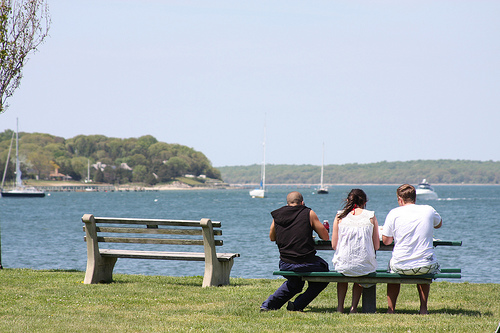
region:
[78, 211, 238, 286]
Cement and wood bench overlooking lake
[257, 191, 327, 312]
Man in black shirt sitting on bench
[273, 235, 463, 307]
Green picnic table near lake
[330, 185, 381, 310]
Lady in white blouse sitting on bench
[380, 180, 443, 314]
Man in white t-shirt sitting on bench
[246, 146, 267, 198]
White sailboat on lake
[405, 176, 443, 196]
White motorboat on lake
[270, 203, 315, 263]
Black shirt on man on picnic table bench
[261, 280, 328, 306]
Blue pants on man on picnic table bench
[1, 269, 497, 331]
Green grass on bank of lake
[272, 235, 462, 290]
a green picnic table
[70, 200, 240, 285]
a gray park bench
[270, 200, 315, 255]
a man's black tank top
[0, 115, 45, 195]
a black and white boat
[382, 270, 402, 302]
the leg of a man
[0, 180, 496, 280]
blue water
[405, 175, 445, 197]
a white boat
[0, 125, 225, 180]
a large section of green trees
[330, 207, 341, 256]
the arm of a woman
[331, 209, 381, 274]
a woman's sleeveless shirt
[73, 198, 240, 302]
Empty, cement park bench.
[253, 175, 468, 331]
Three people sitting at a picnic table.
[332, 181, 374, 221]
Woman with long brown hair.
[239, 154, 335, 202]
Boats traveling in the water.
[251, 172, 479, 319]
Three people eating at a waterside location.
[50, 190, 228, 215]
Blue water in the harbor.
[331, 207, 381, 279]
Flowing white shirt being worn by a woman.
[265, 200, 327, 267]
Black hooded tank top being worn by a man.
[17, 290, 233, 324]
Grass growing on the ground in the park.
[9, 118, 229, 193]
Shoreline covered in growing trees.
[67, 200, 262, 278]
A empty bench by the water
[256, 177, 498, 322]
Three friends sit at a picnic table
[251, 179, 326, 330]
The man is bald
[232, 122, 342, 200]
Sailboats are parked in the water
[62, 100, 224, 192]
The land is full of trees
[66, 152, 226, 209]
There is a small beach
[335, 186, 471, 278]
The woman and man wear white shirts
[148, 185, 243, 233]
The water is calm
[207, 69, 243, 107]
The sky is blue with no clouds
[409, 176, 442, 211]
A speed boat is in the water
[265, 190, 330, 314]
man sitting on a bench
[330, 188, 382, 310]
woman sitting on a bench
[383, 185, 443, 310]
man sitting on a bench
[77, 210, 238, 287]
a wooden park bench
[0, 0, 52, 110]
dead branches on a tree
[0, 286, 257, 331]
short light green grass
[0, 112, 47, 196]
a sail boat with a large mast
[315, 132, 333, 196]
a sail boat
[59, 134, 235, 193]
trees on a shoreline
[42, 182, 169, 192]
a dock at shoreline